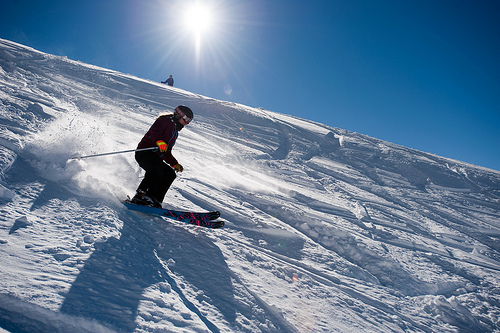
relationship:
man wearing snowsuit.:
[128, 102, 200, 209] [137, 123, 181, 208]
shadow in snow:
[59, 214, 244, 326] [0, 37, 499, 331]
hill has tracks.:
[3, 40, 499, 324] [239, 120, 460, 255]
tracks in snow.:
[239, 120, 460, 255] [0, 37, 499, 331]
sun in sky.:
[137, 5, 251, 81] [1, 0, 497, 173]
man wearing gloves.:
[128, 102, 200, 209] [150, 148, 191, 173]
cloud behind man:
[13, 107, 133, 194] [128, 102, 200, 209]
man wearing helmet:
[128, 102, 200, 209] [169, 102, 198, 131]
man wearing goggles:
[128, 102, 200, 209] [177, 114, 196, 123]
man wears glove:
[128, 102, 200, 209] [154, 138, 172, 153]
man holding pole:
[128, 102, 200, 209] [70, 139, 164, 160]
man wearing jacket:
[128, 102, 200, 209] [139, 112, 184, 164]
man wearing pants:
[128, 102, 200, 209] [133, 154, 178, 205]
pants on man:
[133, 154, 178, 205] [128, 102, 200, 209]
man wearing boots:
[128, 102, 200, 209] [133, 187, 162, 208]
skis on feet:
[126, 200, 220, 228] [131, 185, 170, 208]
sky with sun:
[1, 0, 497, 173] [137, 5, 251, 81]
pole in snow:
[70, 139, 164, 160] [0, 37, 499, 331]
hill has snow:
[3, 40, 499, 324] [0, 37, 499, 331]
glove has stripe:
[154, 135, 174, 156] [156, 146, 169, 147]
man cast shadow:
[128, 102, 200, 209] [59, 214, 244, 326]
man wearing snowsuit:
[128, 102, 200, 209] [137, 123, 181, 208]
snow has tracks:
[0, 37, 499, 331] [101, 191, 499, 331]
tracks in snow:
[101, 191, 499, 331] [0, 37, 499, 331]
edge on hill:
[3, 40, 499, 174] [3, 40, 499, 324]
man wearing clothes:
[128, 96, 200, 206] [137, 123, 181, 208]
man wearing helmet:
[128, 96, 200, 206] [169, 102, 198, 131]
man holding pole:
[128, 96, 200, 206] [70, 144, 159, 160]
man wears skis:
[128, 96, 200, 206] [126, 200, 220, 228]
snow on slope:
[0, 37, 499, 331] [3, 40, 499, 324]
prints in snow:
[129, 106, 499, 328] [0, 37, 499, 331]